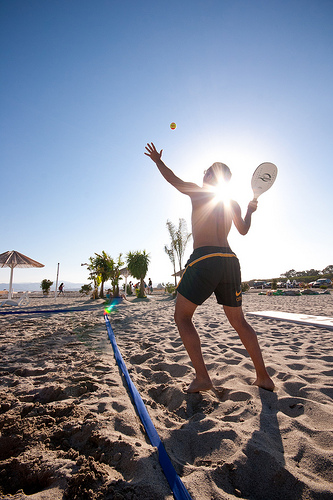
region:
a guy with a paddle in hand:
[126, 115, 310, 400]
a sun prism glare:
[98, 284, 119, 317]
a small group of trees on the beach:
[73, 238, 162, 303]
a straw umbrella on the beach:
[0, 245, 48, 316]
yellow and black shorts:
[168, 231, 265, 333]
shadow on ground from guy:
[122, 367, 317, 498]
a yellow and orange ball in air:
[166, 118, 182, 130]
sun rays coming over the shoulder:
[195, 170, 241, 206]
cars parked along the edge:
[251, 275, 328, 293]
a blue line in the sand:
[103, 297, 184, 497]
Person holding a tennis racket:
[230, 159, 280, 214]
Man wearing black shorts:
[182, 241, 248, 310]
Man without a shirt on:
[177, 179, 238, 243]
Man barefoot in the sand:
[177, 364, 288, 403]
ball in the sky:
[169, 121, 183, 134]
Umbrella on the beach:
[5, 248, 35, 296]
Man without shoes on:
[185, 364, 278, 398]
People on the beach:
[123, 274, 154, 297]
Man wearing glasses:
[199, 165, 213, 180]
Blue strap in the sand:
[92, 302, 156, 476]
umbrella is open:
[0, 250, 44, 299]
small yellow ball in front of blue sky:
[170, 122, 176, 130]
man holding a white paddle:
[143, 143, 287, 392]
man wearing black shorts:
[176, 245, 242, 305]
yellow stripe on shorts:
[177, 252, 238, 290]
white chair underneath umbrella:
[0, 294, 31, 309]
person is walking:
[56, 282, 66, 296]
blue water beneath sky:
[1, 282, 112, 290]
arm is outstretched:
[144, 143, 194, 196]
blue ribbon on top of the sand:
[103, 312, 193, 499]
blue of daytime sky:
[2, 4, 328, 283]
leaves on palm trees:
[95, 251, 148, 294]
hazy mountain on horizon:
[2, 278, 103, 291]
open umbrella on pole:
[1, 248, 43, 298]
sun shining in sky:
[213, 179, 236, 206]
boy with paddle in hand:
[145, 143, 277, 394]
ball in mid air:
[169, 121, 178, 131]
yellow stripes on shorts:
[180, 245, 242, 304]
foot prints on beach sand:
[4, 293, 332, 498]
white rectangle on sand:
[248, 309, 332, 331]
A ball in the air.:
[161, 116, 187, 136]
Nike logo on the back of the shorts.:
[228, 281, 247, 302]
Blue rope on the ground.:
[97, 308, 198, 498]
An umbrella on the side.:
[3, 240, 40, 303]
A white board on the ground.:
[248, 302, 331, 331]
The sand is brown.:
[11, 292, 331, 480]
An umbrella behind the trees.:
[91, 253, 150, 300]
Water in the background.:
[2, 280, 92, 292]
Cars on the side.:
[253, 276, 331, 290]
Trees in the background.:
[243, 259, 331, 286]